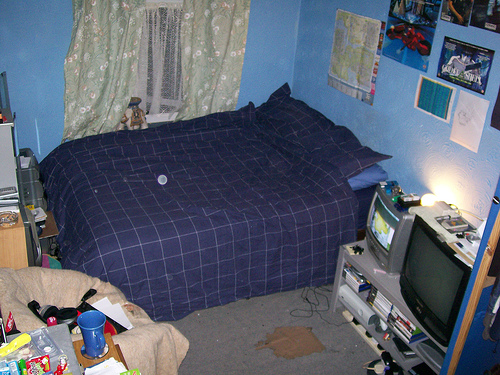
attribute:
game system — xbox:
[336, 289, 387, 328]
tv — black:
[394, 212, 475, 349]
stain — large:
[253, 324, 327, 359]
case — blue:
[254, 82, 337, 142]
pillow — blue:
[347, 169, 387, 191]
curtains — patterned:
[73, 11, 253, 117]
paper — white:
[450, 87, 489, 154]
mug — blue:
[70, 288, 129, 353]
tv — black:
[400, 208, 482, 353]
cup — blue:
[73, 306, 123, 361]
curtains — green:
[162, 7, 245, 115]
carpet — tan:
[192, 311, 258, 373]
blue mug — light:
[77, 314, 117, 362]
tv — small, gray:
[355, 190, 410, 279]